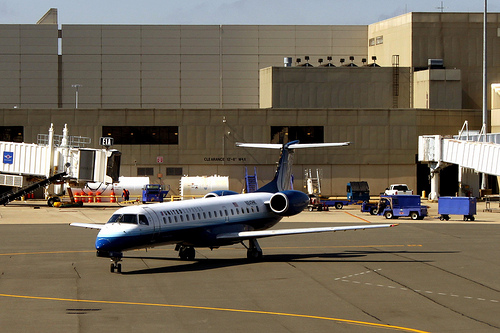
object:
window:
[252, 202, 263, 216]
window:
[208, 206, 220, 223]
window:
[158, 216, 169, 230]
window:
[105, 209, 152, 227]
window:
[201, 209, 207, 220]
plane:
[65, 128, 402, 278]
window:
[178, 197, 238, 219]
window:
[230, 205, 241, 222]